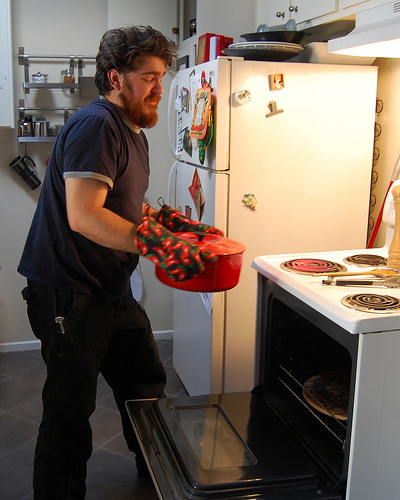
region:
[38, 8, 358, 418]
person with pot near an oven.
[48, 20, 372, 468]
person with a large pot near an oven.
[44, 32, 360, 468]
person with large red pot near the oven.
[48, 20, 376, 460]
man holding a pot near an oven.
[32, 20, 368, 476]
man holding a large pot near the oven.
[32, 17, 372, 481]
man handling a red pot near an oven.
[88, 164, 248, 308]
person holding a red pot.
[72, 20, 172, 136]
a man with a beard.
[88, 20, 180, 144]
man with dark colored hair.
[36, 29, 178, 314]
man wearing a dark colored shirt.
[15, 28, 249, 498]
a man carrying a cooking pot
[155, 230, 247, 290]
a red cooking pot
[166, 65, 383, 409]
a large refrigerator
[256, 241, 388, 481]
a large gas cooker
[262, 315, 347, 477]
an open oven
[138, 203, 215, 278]
red, green and black gloves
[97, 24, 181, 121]
a man with short curly hair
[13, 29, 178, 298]
a man with a black t-shirt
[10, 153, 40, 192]
a bottle hanging on the wall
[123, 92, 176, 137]
brown beard and mustache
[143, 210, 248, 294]
dish is red and hot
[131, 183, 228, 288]
oven mitts are black and red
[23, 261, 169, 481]
man is wearing black pants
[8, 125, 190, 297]
man is wearing a blue shirt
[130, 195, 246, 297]
man is holding red pot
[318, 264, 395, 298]
utensils on top of stove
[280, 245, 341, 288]
burner is red and hot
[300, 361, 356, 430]
pizza is in oven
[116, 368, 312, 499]
over door is black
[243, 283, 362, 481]
oven is wide open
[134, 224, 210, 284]
right hand wearing an oven mitten.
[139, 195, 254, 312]
hands holding a large red pot.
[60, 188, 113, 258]
elbow of a person.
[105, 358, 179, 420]
knee area of a person.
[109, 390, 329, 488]
open door to an oven.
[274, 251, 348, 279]
hot burner on a stove.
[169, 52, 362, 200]
white refrigerator in view.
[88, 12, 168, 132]
person with a full beard.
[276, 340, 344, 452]
food cooking in an oven.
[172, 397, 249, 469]
window to an oven door.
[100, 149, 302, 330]
Red peppers on oven mitts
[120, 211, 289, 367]
Man wearing two oven mitts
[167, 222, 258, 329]
Man carrying red pot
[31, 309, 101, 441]
Man wearing black pants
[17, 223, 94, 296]
Man wearing black shirt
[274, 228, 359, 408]
Stove is white in color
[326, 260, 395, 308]
Silver and black tongs on stove top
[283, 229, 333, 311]
Burner is red hot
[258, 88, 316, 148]
Chip clip on fridge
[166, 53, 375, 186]
Refrigerator is white